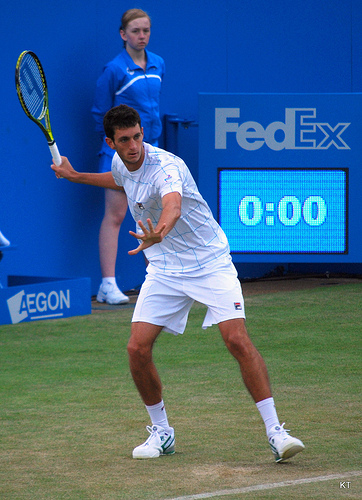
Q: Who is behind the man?
A: A Lady.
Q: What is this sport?
A: Tennis.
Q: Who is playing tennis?
A: A man.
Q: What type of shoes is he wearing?
A: Sneakers.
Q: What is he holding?
A: A tennis racket.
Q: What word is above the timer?
A: FedEx.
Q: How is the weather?
A: Warm.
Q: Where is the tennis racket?
A: His right hand.